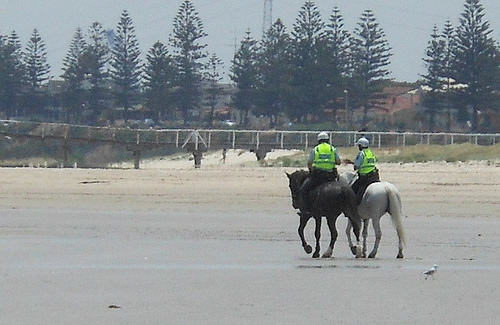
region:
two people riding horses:
[279, 131, 409, 263]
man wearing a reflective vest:
[297, 129, 345, 216]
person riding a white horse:
[338, 138, 405, 263]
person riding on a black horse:
[286, 130, 362, 262]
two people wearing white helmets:
[297, 132, 380, 214]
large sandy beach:
[2, 165, 497, 322]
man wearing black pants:
[295, 133, 342, 213]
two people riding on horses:
[284, 131, 407, 259]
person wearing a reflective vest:
[343, 135, 380, 200]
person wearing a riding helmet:
[296, 131, 343, 215]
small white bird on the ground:
[420, 261, 440, 283]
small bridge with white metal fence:
[0, 117, 499, 166]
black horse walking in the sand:
[282, 168, 362, 263]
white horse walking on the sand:
[337, 169, 407, 263]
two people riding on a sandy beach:
[2, 126, 499, 321]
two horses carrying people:
[282, 167, 411, 264]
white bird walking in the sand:
[420, 260, 441, 285]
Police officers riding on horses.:
[283, 131, 410, 259]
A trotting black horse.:
[286, 166, 363, 260]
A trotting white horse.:
[342, 170, 408, 262]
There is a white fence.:
[1, 125, 499, 147]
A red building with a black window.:
[360, 76, 433, 120]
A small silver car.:
[219, 115, 239, 131]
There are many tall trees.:
[0, 0, 497, 131]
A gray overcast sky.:
[0, 0, 499, 84]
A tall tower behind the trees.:
[253, 0, 288, 81]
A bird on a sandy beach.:
[414, 253, 447, 291]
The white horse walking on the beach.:
[350, 170, 404, 258]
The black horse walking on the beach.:
[279, 161, 351, 253]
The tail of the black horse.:
[339, 183, 361, 241]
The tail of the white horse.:
[383, 184, 408, 245]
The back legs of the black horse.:
[320, 207, 362, 255]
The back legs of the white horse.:
[373, 214, 407, 256]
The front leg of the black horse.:
[297, 208, 314, 253]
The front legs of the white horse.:
[346, 223, 383, 257]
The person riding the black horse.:
[312, 128, 340, 180]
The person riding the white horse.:
[352, 140, 382, 188]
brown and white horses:
[285, 168, 406, 260]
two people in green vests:
[299, 131, 379, 216]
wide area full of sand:
[0, 161, 499, 324]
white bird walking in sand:
[422, 261, 440, 280]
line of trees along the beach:
[0, 2, 497, 138]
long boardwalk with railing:
[1, 117, 499, 171]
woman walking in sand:
[218, 145, 230, 165]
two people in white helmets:
[297, 127, 382, 213]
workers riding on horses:
[285, 131, 406, 262]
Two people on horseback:
[286, 138, 410, 263]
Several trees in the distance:
[235, 33, 391, 126]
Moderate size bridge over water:
[6, 118, 277, 171]